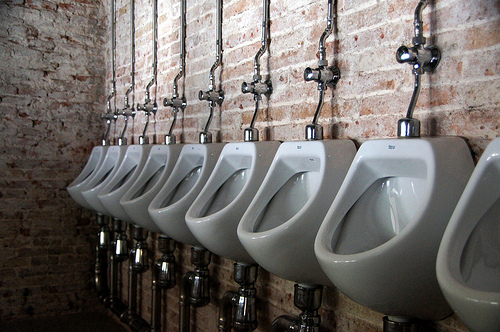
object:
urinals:
[65, 136, 500, 332]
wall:
[3, 0, 106, 332]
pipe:
[395, 0, 442, 140]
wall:
[102, 7, 497, 141]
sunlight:
[135, 4, 174, 114]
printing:
[294, 145, 396, 149]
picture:
[0, 0, 500, 332]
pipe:
[90, 213, 112, 322]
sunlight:
[268, 138, 433, 212]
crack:
[24, 57, 72, 90]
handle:
[303, 66, 339, 91]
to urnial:
[397, 117, 421, 139]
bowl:
[313, 134, 477, 322]